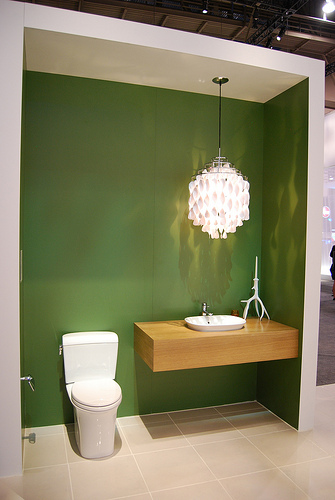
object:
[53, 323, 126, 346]
lid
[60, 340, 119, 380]
tank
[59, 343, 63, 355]
handle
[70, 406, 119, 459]
toilet base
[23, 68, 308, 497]
bathroom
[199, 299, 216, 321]
faucet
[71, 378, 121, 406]
lid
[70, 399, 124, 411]
toilet seat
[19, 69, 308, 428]
walls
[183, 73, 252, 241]
hanging light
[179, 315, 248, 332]
sink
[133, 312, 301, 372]
shelf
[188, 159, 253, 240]
chandelier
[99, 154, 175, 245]
wall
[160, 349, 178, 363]
wood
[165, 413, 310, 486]
tiles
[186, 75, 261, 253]
lamp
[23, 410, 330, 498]
tiles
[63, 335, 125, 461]
toilet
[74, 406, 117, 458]
base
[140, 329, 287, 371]
counter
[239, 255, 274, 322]
decoration